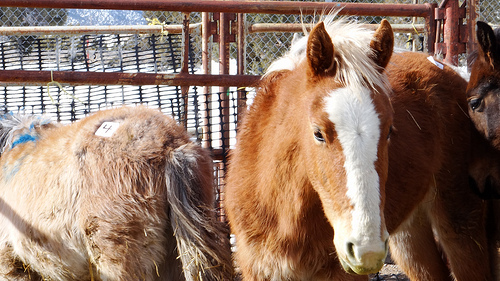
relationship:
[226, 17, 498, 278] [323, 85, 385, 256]
horse has patch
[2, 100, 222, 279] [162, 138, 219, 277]
animal has tail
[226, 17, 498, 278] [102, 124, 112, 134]
horse has 4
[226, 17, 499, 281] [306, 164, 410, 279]
horse has nose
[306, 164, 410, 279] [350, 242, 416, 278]
nose has tip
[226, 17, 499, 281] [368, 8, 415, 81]
horse has ear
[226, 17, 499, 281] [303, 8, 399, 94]
horse has mane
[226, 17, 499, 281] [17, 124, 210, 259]
horse has fur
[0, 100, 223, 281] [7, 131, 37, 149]
animal has spot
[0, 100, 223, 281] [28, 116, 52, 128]
animal has spot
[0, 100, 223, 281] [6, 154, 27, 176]
animal has spot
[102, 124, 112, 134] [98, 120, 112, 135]
4 with 4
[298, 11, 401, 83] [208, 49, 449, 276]
ears on a horse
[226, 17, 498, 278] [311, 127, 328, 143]
horse with eye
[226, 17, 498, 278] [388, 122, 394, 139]
horse with eye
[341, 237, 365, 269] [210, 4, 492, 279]
nostril of horse